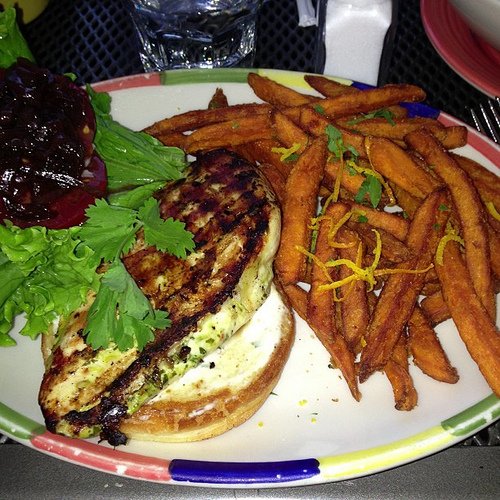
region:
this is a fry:
[437, 232, 499, 353]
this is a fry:
[356, 143, 441, 208]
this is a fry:
[314, 70, 417, 115]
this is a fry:
[278, 120, 326, 299]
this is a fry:
[314, 133, 381, 205]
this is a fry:
[416, 140, 495, 310]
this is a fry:
[301, 172, 441, 280]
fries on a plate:
[438, 238, 497, 359]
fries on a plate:
[366, 251, 439, 353]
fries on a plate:
[179, 110, 281, 160]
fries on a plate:
[300, 65, 419, 110]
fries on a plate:
[203, 79, 234, 107]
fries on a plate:
[155, 96, 263, 148]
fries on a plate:
[320, 353, 355, 399]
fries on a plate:
[432, 111, 474, 145]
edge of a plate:
[376, 382, 380, 399]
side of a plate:
[268, 427, 298, 451]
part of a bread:
[213, 404, 226, 419]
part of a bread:
[268, 359, 287, 384]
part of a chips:
[348, 318, 375, 340]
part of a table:
[471, 457, 473, 459]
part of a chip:
[395, 318, 397, 324]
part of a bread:
[183, 367, 222, 412]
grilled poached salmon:
[37, 143, 284, 441]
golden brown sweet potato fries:
[136, 71, 498, 408]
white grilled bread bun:
[30, 221, 301, 436]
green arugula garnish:
[1, 80, 198, 356]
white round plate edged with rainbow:
[0, 55, 498, 483]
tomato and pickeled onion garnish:
[7, 47, 114, 229]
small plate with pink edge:
[409, 0, 493, 107]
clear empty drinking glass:
[115, 0, 254, 82]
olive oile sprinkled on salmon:
[72, 240, 289, 442]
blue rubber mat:
[25, 0, 487, 90]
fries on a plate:
[186, 102, 293, 152]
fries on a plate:
[138, 104, 216, 135]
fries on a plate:
[275, 152, 333, 252]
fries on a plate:
[308, 287, 370, 363]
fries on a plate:
[373, 325, 468, 425]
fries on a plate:
[365, 182, 457, 307]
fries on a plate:
[373, 140, 439, 195]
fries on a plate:
[343, 105, 447, 145]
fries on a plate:
[332, 73, 437, 127]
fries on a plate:
[308, 67, 365, 102]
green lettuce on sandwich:
[43, 243, 93, 283]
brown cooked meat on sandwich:
[178, 294, 222, 329]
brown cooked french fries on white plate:
[278, 144, 321, 253]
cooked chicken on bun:
[49, 159, 271, 426]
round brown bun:
[42, 234, 289, 431]